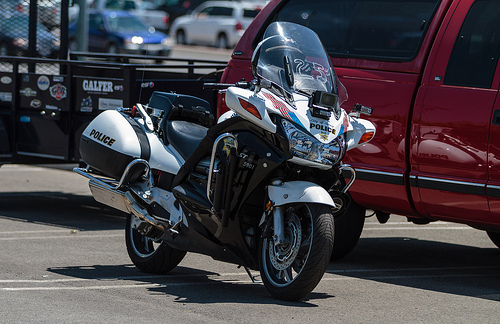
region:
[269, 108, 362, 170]
a headlight on a motorcycle.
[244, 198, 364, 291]
a front motorcycle wheel.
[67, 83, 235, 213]
a seat on a motorcycle.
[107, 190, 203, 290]
a back tire on a motorcycle.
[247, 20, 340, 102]
a windshield on a motorcycle.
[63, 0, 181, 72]
a small blue car.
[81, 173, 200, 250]
an exhaust on a motorcycle.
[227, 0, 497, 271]
a red parked truck.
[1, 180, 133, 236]
a shadow cast onto a road.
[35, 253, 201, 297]
a small shadow.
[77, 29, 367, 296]
a parked police motorcycle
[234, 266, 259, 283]
the kickstand for the motorcycle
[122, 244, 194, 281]
the rear tire of the bike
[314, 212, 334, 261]
the tread on the front tire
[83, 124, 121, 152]
the police logo on the back of the motorcycle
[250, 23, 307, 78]
the helmet behind the windshield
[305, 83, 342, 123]
the lights on the fronmt of the motorcycle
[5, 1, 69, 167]
the trailer on the back of the truck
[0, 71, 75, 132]
the sticker on the back of the black trailer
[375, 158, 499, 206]
the black trim on the red truck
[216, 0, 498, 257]
The truck is red.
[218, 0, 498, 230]
The truck is only partially visible.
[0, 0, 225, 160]
The truck is carrying a trailer.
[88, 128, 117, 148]
The word police is on the motorcycle.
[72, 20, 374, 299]
The motorcycle is black and white.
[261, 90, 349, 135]
The motorcycle has american flags on it.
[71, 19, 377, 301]
The motorcycle is parked.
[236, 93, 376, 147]
There are red lights on the motorcycle.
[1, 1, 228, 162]
The trailer is black.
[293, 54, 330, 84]
The number 25 is written on the window.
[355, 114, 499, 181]
Reflection of bike in side of vehicle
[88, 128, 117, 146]
Police printed on side of bike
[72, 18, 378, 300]
Black and white law enforcement bike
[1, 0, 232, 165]
Trailer attached to back of vehicle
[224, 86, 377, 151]
Turning signals on front of bike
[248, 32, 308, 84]
Helmet sitting on front of bike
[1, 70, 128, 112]
A bunch of stickers on side of the trailer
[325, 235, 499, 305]
Shadow under the vehicle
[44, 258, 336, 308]
Shadow of motorcycle cast on the street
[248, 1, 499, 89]
Dark tinted windows on the truck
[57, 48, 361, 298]
a police motorcycle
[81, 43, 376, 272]
a motorcycle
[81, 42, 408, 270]
a black and white motorcycle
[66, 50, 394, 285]
a white and black motorcycle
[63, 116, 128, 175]
a police sticker on a motorcycle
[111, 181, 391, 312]
two black tires on a motorcycle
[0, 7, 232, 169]
a black trailer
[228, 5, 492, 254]
a red truck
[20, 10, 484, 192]
a red truck pulling a black trailer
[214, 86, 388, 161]
orange lights on a police motorcycle